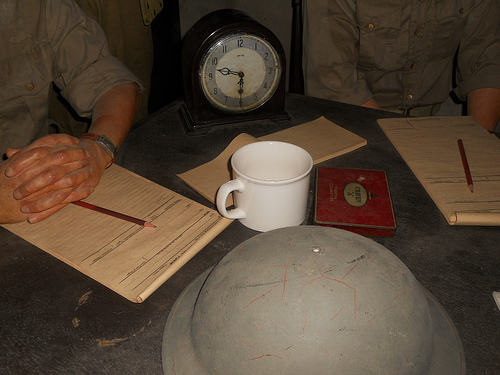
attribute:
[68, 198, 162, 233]
pencil — red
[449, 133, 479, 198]
pencil — red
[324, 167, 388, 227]
box — red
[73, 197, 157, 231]
pencil — red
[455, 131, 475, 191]
pencil — red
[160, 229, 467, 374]
hat — gray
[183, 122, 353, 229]
cup — white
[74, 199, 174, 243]
pencil — red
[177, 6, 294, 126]
clock — wooden, mantle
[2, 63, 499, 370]
table — dark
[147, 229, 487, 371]
hat — white, hard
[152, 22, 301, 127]
clock — brown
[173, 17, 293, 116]
face — clock, gray and white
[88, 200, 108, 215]
pencil — red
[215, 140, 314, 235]
mug — white, ceramic, coffee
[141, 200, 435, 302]
elements — old-fashioned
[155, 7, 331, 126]
clock — old-fashioned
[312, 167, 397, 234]
box — red